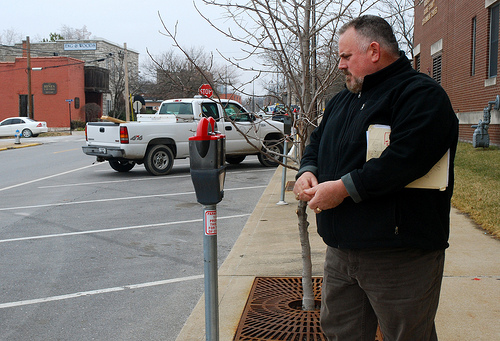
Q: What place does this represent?
A: It represents the sidewalk.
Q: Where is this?
A: This is at the sidewalk.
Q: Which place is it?
A: It is a sidewalk.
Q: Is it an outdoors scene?
A: Yes, it is outdoors.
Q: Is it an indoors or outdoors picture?
A: It is outdoors.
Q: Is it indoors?
A: No, it is outdoors.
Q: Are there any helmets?
A: No, there are no helmets.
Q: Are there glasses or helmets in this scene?
A: No, there are no helmets or glasses.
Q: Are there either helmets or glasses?
A: No, there are no helmets or glasses.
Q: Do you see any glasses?
A: No, there are no glasses.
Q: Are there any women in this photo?
A: No, there are no women.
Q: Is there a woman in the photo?
A: No, there are no women.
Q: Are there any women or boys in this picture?
A: No, there are no women or boys.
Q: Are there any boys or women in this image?
A: No, there are no women or boys.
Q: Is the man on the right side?
A: Yes, the man is on the right of the image.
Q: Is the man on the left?
A: No, the man is on the right of the image.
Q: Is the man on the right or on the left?
A: The man is on the right of the image.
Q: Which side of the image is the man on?
A: The man is on the right of the image.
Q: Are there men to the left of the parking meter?
A: No, the man is to the right of the parking meter.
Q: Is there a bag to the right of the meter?
A: No, there is a man to the right of the meter.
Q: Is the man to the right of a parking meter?
A: Yes, the man is to the right of a parking meter.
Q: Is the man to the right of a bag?
A: No, the man is to the right of a parking meter.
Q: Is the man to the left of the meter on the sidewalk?
A: No, the man is to the right of the meter.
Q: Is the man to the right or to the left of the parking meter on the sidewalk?
A: The man is to the right of the parking meter.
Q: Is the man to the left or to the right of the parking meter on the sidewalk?
A: The man is to the right of the parking meter.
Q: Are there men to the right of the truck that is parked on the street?
A: Yes, there is a man to the right of the truck.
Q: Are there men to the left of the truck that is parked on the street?
A: No, the man is to the right of the truck.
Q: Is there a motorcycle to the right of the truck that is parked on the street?
A: No, there is a man to the right of the truck.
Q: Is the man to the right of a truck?
A: Yes, the man is to the right of a truck.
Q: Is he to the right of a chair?
A: No, the man is to the right of a truck.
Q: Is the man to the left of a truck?
A: No, the man is to the right of a truck.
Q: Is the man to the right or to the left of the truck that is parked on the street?
A: The man is to the right of the truck.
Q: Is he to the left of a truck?
A: No, the man is to the right of a truck.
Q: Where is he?
A: The man is on the sidewalk.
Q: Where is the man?
A: The man is on the sidewalk.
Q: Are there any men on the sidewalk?
A: Yes, there is a man on the sidewalk.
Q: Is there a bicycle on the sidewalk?
A: No, there is a man on the sidewalk.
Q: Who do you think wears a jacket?
A: The man wears a jacket.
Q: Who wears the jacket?
A: The man wears a jacket.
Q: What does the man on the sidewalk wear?
A: The man wears a jacket.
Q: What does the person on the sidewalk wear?
A: The man wears a jacket.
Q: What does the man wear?
A: The man wears a jacket.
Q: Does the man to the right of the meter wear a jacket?
A: Yes, the man wears a jacket.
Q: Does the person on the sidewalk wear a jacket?
A: Yes, the man wears a jacket.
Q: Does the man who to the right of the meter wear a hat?
A: No, the man wears a jacket.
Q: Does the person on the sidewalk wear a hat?
A: No, the man wears a jacket.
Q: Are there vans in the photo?
A: No, there are no vans.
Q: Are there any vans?
A: No, there are no vans.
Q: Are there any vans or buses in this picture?
A: No, there are no vans or buses.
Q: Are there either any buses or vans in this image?
A: No, there are no vans or buses.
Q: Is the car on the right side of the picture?
A: No, the car is on the left of the image.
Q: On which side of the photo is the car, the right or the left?
A: The car is on the left of the image.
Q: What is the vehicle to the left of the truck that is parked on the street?
A: The vehicle is a car.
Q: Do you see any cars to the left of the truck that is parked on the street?
A: Yes, there is a car to the left of the truck.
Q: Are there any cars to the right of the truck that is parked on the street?
A: No, the car is to the left of the truck.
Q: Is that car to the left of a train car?
A: No, the car is to the left of a truck.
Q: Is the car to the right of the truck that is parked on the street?
A: No, the car is to the left of the truck.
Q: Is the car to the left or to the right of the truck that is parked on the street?
A: The car is to the left of the truck.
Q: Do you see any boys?
A: No, there are no boys.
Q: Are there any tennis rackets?
A: No, there are no tennis rackets.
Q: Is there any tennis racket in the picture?
A: No, there are no rackets.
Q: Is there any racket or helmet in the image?
A: No, there are no rackets or helmets.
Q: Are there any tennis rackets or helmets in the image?
A: No, there are no tennis rackets or helmets.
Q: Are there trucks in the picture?
A: Yes, there is a truck.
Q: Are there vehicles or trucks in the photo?
A: Yes, there is a truck.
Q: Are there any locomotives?
A: No, there are no locomotives.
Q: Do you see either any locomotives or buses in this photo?
A: No, there are no locomotives or buses.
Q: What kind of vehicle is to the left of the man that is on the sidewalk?
A: The vehicle is a truck.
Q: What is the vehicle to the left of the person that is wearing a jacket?
A: The vehicle is a truck.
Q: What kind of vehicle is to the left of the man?
A: The vehicle is a truck.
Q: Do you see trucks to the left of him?
A: Yes, there is a truck to the left of the man.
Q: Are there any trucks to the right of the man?
A: No, the truck is to the left of the man.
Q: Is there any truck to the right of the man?
A: No, the truck is to the left of the man.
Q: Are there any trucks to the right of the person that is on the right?
A: No, the truck is to the left of the man.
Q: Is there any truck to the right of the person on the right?
A: No, the truck is to the left of the man.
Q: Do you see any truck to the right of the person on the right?
A: No, the truck is to the left of the man.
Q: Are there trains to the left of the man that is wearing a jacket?
A: No, there is a truck to the left of the man.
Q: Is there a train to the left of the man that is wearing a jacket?
A: No, there is a truck to the left of the man.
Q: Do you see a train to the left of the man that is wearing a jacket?
A: No, there is a truck to the left of the man.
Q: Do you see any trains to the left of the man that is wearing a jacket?
A: No, there is a truck to the left of the man.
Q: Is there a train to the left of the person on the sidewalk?
A: No, there is a truck to the left of the man.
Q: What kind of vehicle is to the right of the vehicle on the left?
A: The vehicle is a truck.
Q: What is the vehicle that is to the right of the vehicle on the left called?
A: The vehicle is a truck.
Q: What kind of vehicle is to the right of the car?
A: The vehicle is a truck.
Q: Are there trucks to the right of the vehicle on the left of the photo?
A: Yes, there is a truck to the right of the car.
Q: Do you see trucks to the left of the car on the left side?
A: No, the truck is to the right of the car.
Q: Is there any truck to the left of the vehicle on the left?
A: No, the truck is to the right of the car.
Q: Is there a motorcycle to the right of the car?
A: No, there is a truck to the right of the car.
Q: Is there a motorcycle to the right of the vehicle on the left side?
A: No, there is a truck to the right of the car.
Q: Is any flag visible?
A: No, there are no flags.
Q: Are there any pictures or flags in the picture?
A: No, there are no flags or pictures.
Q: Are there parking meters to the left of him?
A: Yes, there is a parking meter to the left of the man.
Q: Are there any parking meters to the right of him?
A: No, the parking meter is to the left of the man.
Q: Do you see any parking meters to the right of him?
A: No, the parking meter is to the left of the man.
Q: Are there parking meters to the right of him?
A: No, the parking meter is to the left of the man.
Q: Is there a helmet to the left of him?
A: No, there is a parking meter to the left of the man.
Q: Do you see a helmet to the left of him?
A: No, there is a parking meter to the left of the man.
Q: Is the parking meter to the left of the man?
A: Yes, the parking meter is to the left of the man.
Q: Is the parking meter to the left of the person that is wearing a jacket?
A: Yes, the parking meter is to the left of the man.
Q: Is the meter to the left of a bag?
A: No, the meter is to the left of the man.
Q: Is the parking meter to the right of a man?
A: No, the parking meter is to the left of a man.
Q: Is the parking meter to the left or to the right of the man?
A: The parking meter is to the left of the man.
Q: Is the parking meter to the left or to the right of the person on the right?
A: The parking meter is to the left of the man.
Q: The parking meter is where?
A: The parking meter is on the sidewalk.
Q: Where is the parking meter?
A: The parking meter is on the sidewalk.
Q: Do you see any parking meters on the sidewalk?
A: Yes, there is a parking meter on the sidewalk.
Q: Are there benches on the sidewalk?
A: No, there is a parking meter on the sidewalk.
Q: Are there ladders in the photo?
A: No, there are no ladders.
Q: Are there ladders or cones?
A: No, there are no ladders or cones.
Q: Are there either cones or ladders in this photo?
A: No, there are no ladders or cones.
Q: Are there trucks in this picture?
A: Yes, there is a truck.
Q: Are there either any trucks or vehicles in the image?
A: Yes, there is a truck.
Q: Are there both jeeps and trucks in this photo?
A: No, there is a truck but no jeeps.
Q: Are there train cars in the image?
A: No, there are no train cars.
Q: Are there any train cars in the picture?
A: No, there are no train cars.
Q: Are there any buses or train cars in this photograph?
A: No, there are no train cars or buses.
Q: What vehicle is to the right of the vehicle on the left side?
A: The vehicle is a truck.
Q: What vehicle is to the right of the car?
A: The vehicle is a truck.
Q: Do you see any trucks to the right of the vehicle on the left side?
A: Yes, there is a truck to the right of the car.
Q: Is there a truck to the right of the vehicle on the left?
A: Yes, there is a truck to the right of the car.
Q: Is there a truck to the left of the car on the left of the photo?
A: No, the truck is to the right of the car.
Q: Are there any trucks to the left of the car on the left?
A: No, the truck is to the right of the car.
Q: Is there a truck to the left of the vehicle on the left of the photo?
A: No, the truck is to the right of the car.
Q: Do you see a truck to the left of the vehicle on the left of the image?
A: No, the truck is to the right of the car.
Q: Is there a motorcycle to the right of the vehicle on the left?
A: No, there is a truck to the right of the car.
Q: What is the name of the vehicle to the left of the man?
A: The vehicle is a truck.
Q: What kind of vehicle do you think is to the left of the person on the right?
A: The vehicle is a truck.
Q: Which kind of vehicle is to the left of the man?
A: The vehicle is a truck.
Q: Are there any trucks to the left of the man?
A: Yes, there is a truck to the left of the man.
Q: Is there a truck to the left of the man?
A: Yes, there is a truck to the left of the man.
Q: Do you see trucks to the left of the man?
A: Yes, there is a truck to the left of the man.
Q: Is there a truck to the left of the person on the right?
A: Yes, there is a truck to the left of the man.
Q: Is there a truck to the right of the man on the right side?
A: No, the truck is to the left of the man.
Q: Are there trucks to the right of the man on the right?
A: No, the truck is to the left of the man.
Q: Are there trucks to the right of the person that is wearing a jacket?
A: No, the truck is to the left of the man.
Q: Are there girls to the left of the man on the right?
A: No, there is a truck to the left of the man.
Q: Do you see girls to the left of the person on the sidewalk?
A: No, there is a truck to the left of the man.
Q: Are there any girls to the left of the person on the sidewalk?
A: No, there is a truck to the left of the man.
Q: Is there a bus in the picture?
A: No, there are no buses.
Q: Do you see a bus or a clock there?
A: No, there are no buses or clocks.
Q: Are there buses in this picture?
A: No, there are no buses.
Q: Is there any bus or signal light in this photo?
A: No, there are no buses or traffic lights.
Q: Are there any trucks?
A: Yes, there is a truck.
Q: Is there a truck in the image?
A: Yes, there is a truck.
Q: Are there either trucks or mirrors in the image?
A: Yes, there is a truck.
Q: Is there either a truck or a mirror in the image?
A: Yes, there is a truck.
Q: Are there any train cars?
A: No, there are no train cars.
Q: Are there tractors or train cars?
A: No, there are no train cars or tractors.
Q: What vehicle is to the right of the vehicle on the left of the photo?
A: The vehicle is a truck.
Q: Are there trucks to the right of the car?
A: Yes, there is a truck to the right of the car.